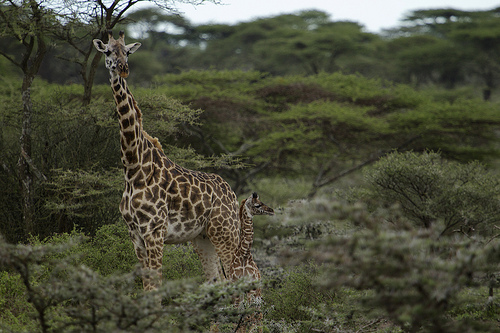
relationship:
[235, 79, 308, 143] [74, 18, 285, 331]
trees surrounding giraffe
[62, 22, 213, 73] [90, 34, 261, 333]
ears of zebra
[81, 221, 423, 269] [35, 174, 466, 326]
brush on ground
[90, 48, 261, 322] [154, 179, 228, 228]
zebra has spots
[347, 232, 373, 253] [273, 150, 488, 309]
off-green color to bushes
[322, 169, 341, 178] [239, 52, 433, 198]
black branch on tree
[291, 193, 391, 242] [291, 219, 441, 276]
white moss on tree top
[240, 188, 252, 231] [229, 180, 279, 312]
brown comb on baby giraffe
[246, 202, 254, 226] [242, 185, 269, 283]
small stripes on baby giraffe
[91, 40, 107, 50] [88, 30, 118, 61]
black spot in ear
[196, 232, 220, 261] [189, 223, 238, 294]
white under side of leg